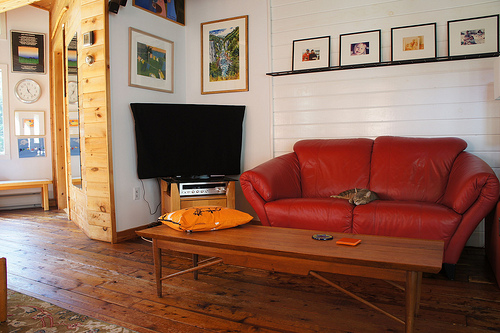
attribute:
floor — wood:
[1, 202, 498, 329]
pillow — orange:
[163, 185, 277, 245]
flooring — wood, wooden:
[1, 207, 499, 331]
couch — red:
[237, 132, 492, 271]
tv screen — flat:
[133, 100, 245, 178]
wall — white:
[188, 7, 498, 201]